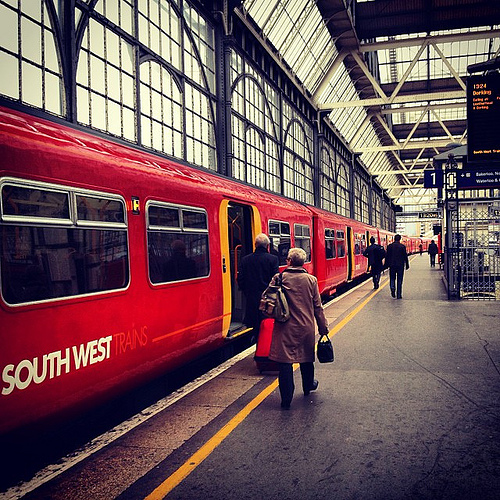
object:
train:
[0, 105, 388, 438]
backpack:
[261, 282, 291, 320]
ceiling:
[323, 19, 497, 155]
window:
[141, 225, 218, 289]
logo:
[1, 323, 148, 399]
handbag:
[317, 335, 335, 365]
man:
[236, 232, 283, 351]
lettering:
[1, 334, 113, 400]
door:
[219, 197, 261, 350]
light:
[131, 197, 141, 213]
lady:
[257, 246, 331, 406]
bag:
[254, 316, 275, 356]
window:
[85, 51, 107, 104]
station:
[1, 0, 500, 496]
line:
[169, 413, 239, 484]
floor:
[229, 441, 474, 500]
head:
[286, 247, 307, 267]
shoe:
[302, 378, 320, 396]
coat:
[258, 268, 328, 359]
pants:
[277, 342, 317, 401]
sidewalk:
[338, 297, 421, 487]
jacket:
[238, 253, 282, 302]